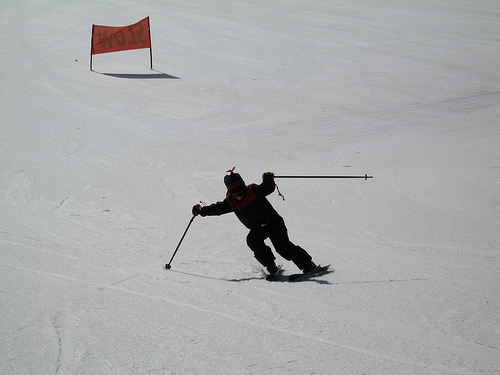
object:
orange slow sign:
[90, 14, 155, 76]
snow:
[4, 4, 496, 372]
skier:
[194, 168, 325, 283]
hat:
[224, 167, 247, 195]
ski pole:
[269, 173, 376, 182]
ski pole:
[164, 215, 196, 273]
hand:
[192, 204, 202, 215]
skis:
[289, 264, 330, 282]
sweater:
[201, 182, 284, 229]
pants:
[245, 223, 313, 272]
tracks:
[82, 280, 177, 304]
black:
[273, 229, 286, 244]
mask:
[230, 189, 248, 203]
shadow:
[227, 276, 338, 290]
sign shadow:
[98, 70, 184, 81]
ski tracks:
[261, 86, 486, 169]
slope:
[2, 2, 490, 166]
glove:
[261, 170, 276, 184]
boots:
[292, 255, 319, 273]